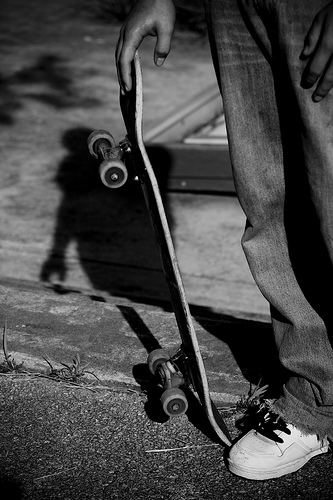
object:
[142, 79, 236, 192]
railing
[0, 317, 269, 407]
grass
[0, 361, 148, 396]
cracks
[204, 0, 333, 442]
jeans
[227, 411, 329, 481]
shoe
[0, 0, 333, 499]
ground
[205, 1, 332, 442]
pant leg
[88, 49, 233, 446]
skateboard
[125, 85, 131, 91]
fingertips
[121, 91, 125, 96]
fingertips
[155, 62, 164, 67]
fingertips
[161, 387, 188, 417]
wheel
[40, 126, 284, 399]
shadow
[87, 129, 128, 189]
wheels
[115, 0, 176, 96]
hand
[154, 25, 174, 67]
thumb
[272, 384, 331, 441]
hem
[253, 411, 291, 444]
lace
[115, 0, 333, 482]
boy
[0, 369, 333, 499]
cement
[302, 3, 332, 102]
hand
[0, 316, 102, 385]
plants